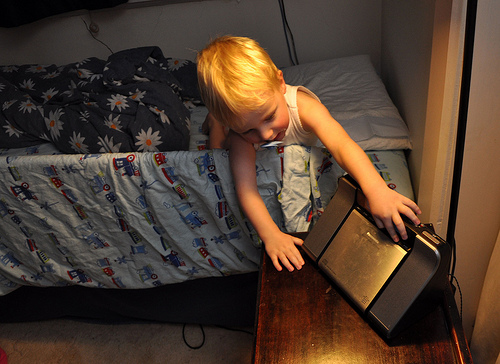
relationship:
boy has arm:
[197, 33, 421, 271] [304, 91, 416, 227]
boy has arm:
[197, 33, 421, 271] [233, 137, 273, 247]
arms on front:
[223, 87, 423, 271] [11, 169, 498, 276]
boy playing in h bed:
[193, 32, 423, 272] [0, 43, 416, 325]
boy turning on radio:
[193, 32, 423, 272] [300, 172, 451, 344]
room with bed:
[6, 5, 498, 360] [3, 55, 419, 295]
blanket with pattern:
[26, 61, 240, 166] [95, 87, 161, 153]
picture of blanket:
[43, 161, 98, 237] [4, 138, 308, 278]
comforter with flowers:
[0, 45, 339, 297] [102, 92, 130, 112]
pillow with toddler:
[103, 2, 304, 76] [184, 35, 429, 273]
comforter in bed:
[0, 57, 325, 298] [3, 55, 419, 295]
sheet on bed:
[2, 155, 415, 297] [3, 55, 419, 295]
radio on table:
[300, 172, 451, 344] [250, 232, 470, 362]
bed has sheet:
[0, 43, 416, 325] [2, 155, 415, 297]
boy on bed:
[193, 32, 423, 272] [0, 43, 416, 325]